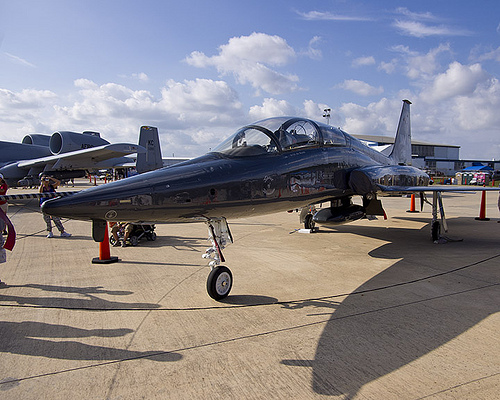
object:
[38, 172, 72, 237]
person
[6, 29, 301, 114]
clouds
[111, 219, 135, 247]
kid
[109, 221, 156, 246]
stroller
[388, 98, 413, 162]
tail wing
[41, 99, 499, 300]
plane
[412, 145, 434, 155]
windows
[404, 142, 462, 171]
building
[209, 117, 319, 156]
windshield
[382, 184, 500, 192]
wing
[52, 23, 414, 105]
sky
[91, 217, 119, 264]
cone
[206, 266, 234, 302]
tire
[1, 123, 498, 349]
airport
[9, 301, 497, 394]
ground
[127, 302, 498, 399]
plane